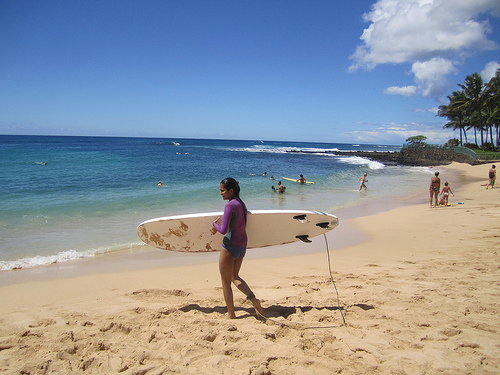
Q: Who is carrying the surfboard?
A: The woman.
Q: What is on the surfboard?
A: Fins.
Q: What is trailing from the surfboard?
A: The board leash.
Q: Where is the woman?
A: At the beach.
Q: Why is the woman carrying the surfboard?
A: To surf.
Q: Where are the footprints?
A: In the sand.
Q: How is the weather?
A: Sunny.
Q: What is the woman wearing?
A: A wet suit.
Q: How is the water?
A: Calm.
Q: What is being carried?
A: Surfboard.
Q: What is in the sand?
A: Footprints.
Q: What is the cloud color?
A: White.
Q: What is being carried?
A: Surfboard.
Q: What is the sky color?
A: Blue.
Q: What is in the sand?
A: Footpritns.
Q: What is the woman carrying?
A: A surfboard.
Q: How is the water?
A: Clear.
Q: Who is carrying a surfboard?
A: The woman.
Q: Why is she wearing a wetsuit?
A: She is going in the water.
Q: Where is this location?
A: On the beach.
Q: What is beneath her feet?
A: Sand.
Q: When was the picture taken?
A: Daytime.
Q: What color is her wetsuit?
A: Purple.